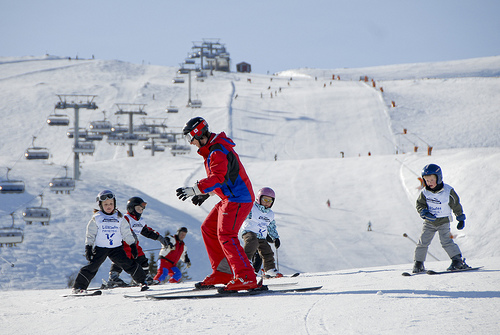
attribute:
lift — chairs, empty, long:
[91, 49, 220, 130]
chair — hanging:
[35, 110, 74, 140]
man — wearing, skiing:
[166, 122, 271, 277]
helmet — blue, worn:
[176, 109, 215, 145]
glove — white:
[165, 180, 207, 213]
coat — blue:
[199, 151, 248, 210]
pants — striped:
[209, 215, 287, 293]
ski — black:
[188, 294, 300, 313]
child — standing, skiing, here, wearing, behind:
[412, 163, 497, 289]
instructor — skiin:
[171, 116, 261, 216]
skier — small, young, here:
[252, 190, 295, 256]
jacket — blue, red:
[202, 131, 272, 227]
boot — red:
[209, 243, 263, 293]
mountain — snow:
[84, 39, 387, 149]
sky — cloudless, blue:
[258, 13, 372, 66]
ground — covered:
[265, 108, 328, 166]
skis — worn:
[146, 267, 292, 314]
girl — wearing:
[255, 189, 297, 248]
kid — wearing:
[120, 191, 146, 233]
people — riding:
[90, 182, 204, 281]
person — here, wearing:
[244, 180, 308, 265]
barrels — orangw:
[355, 73, 427, 155]